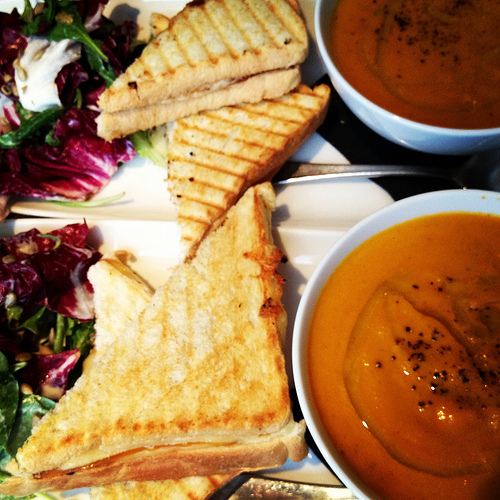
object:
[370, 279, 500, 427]
condiment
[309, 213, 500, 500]
soup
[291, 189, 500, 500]
bowl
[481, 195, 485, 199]
soup stains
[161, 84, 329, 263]
bread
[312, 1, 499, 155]
bowl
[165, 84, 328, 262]
lines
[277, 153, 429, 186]
spoon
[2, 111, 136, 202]
lettuce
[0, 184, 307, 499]
sandwich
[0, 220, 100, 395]
vegetable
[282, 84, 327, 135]
crust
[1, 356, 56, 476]
leaves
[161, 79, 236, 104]
cheese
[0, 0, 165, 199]
salad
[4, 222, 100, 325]
cabbage